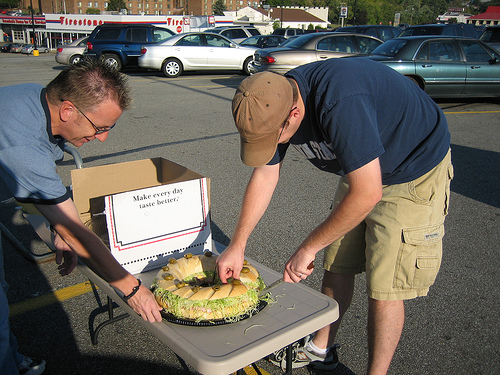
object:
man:
[212, 59, 454, 375]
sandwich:
[149, 252, 267, 323]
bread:
[154, 251, 259, 320]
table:
[24, 218, 338, 375]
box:
[69, 156, 214, 276]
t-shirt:
[265, 56, 450, 185]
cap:
[231, 71, 294, 167]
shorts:
[322, 145, 454, 303]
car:
[138, 31, 263, 78]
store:
[0, 14, 46, 48]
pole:
[28, 0, 40, 59]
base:
[32, 50, 39, 57]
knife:
[257, 260, 315, 297]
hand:
[283, 248, 316, 283]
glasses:
[61, 99, 117, 136]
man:
[1, 61, 164, 374]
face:
[70, 101, 122, 150]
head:
[231, 70, 305, 145]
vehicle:
[340, 36, 500, 104]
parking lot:
[46, 16, 498, 117]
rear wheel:
[100, 52, 123, 73]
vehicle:
[82, 25, 177, 74]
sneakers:
[267, 334, 340, 370]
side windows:
[412, 38, 463, 63]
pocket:
[393, 226, 446, 290]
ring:
[299, 274, 303, 278]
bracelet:
[123, 278, 143, 300]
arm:
[0, 143, 163, 325]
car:
[247, 31, 384, 77]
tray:
[148, 285, 268, 327]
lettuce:
[242, 323, 265, 334]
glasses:
[278, 107, 297, 142]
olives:
[163, 272, 174, 281]